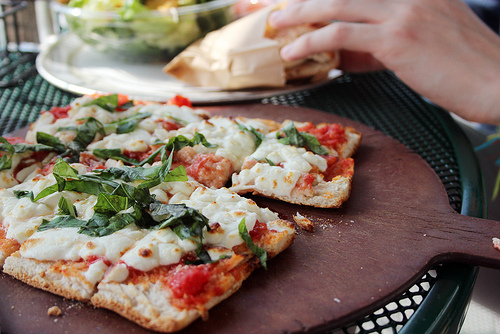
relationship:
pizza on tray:
[3, 93, 498, 333] [1, 97, 496, 332]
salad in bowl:
[55, 1, 210, 51] [47, 0, 242, 70]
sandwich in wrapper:
[267, 7, 342, 81] [156, 8, 295, 88]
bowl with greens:
[47, 0, 242, 70] [95, 8, 217, 50]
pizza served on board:
[3, 93, 498, 333] [14, 100, 482, 322]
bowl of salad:
[47, 0, 242, 70] [67, 2, 228, 65]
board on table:
[142, 103, 479, 294] [5, 28, 468, 328]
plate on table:
[27, 27, 356, 116] [5, 28, 468, 328]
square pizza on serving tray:
[57, 80, 350, 249] [8, 87, 482, 317]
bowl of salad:
[47, 0, 242, 70] [83, 6, 228, 49]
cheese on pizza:
[61, 223, 151, 273] [3, 84, 348, 294]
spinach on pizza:
[45, 160, 199, 230] [3, 93, 498, 333]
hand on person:
[264, 0, 499, 124] [263, 1, 499, 122]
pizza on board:
[3, 93, 498, 333] [2, 98, 498, 332]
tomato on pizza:
[160, 260, 212, 310] [3, 93, 498, 333]